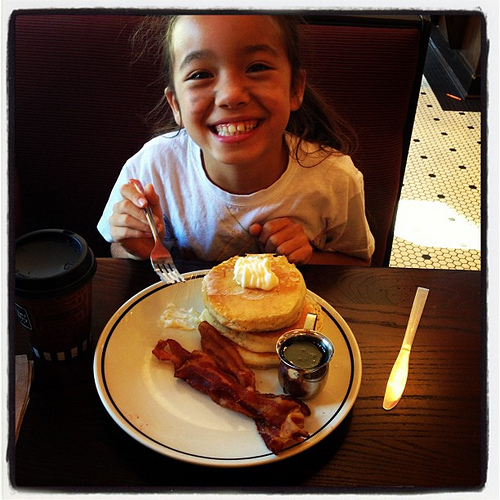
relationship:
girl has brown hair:
[85, 15, 385, 257] [291, 36, 301, 76]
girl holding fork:
[85, 15, 385, 257] [148, 225, 182, 283]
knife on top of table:
[365, 278, 440, 418] [370, 450, 438, 484]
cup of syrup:
[276, 327, 340, 390] [289, 339, 318, 364]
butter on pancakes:
[228, 254, 285, 292] [202, 251, 315, 333]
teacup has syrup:
[276, 327, 340, 390] [289, 339, 318, 364]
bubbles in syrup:
[299, 346, 311, 357] [289, 339, 318, 364]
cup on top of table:
[276, 327, 340, 390] [10, 257, 483, 489]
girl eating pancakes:
[85, 15, 385, 257] [202, 251, 315, 333]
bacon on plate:
[159, 331, 242, 393] [146, 276, 188, 294]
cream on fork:
[156, 269, 181, 282] [148, 225, 182, 283]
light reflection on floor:
[406, 204, 468, 257] [420, 140, 465, 185]